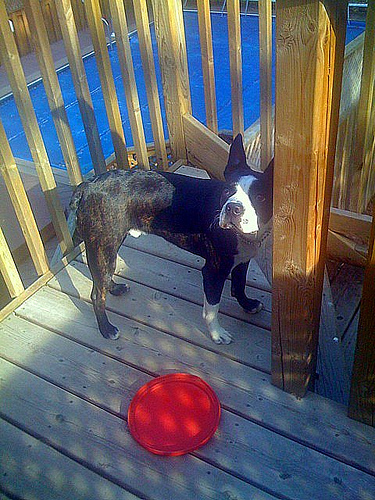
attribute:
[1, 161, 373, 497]
floor — wood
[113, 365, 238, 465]
frisbee — red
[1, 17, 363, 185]
water — blue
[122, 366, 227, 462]
frisbee — red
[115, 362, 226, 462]
frisbee — red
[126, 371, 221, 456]
frisbee — red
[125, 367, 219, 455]
bucket top — red, plastic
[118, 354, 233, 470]
frisbee — red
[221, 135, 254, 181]
ear — pointy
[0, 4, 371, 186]
pool — swimming pool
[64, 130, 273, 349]
dog — black, white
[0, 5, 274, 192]
swimming pool — in ground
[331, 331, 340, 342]
bolt — galvanized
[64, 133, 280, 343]
bulldog — black, white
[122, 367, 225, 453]
frisbee — red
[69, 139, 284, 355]
dog — white, black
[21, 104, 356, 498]
deck — wooden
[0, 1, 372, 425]
railing — wooden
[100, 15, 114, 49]
ladder — swimming pool ladder, metallic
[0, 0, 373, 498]
deck — wooden